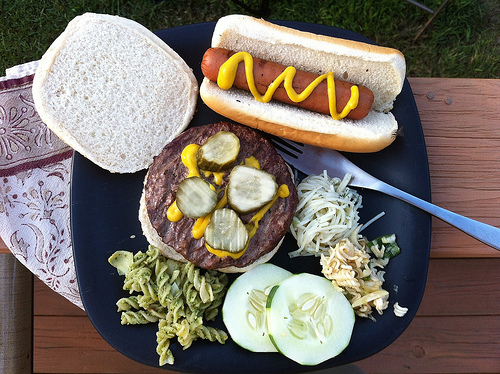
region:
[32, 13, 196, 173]
Plain hamburger bun top on plate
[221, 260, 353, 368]
Cucumber slices sitting on plate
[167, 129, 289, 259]
Pickes and mustard on top of hamburger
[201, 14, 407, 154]
Hotdog with mustard in a bun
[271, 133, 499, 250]
Fork sitting on side of plate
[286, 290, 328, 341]
Seeds in middle of cucumber slice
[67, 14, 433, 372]
Food sitting on blue plate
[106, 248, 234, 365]
Pasta salad sitting on blue plate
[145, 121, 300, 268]
Hamburger patty sitting on bun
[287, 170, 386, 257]
Plain noodles sitting on plate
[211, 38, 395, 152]
hot dog on bun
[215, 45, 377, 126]
mustard on hot dog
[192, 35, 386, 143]
bun is white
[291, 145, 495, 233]
steel spoon on blue plate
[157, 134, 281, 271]
brown hamburger on bun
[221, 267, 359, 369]
green and sliced cucumbers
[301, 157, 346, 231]
white noodles on plate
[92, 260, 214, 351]
light green pasta salad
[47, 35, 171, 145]
half of white bun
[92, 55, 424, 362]
plate on wooden table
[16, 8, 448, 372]
A plate with hamburger and hotdog on it.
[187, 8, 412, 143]
A hotdog on a bun with mustard.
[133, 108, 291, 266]
A hamburger on a bun with pickles and mustard.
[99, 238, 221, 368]
Small amount of pasta salad.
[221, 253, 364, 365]
Two slices of cucumbers.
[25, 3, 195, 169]
The top of a hamburger bun with nothing on it.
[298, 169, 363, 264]
Small amount of cole slaw.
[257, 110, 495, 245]
A silver fork.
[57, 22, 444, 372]
A square plate with rounded edges.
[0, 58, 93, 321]
A napkin under the plate with a pattern on it.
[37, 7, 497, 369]
a plate with food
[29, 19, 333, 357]
a plate on a table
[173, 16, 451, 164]
a hotdog on a plate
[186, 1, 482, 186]
a hotdog on a bun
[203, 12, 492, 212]
a hotdog with mustard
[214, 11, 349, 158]
mustard on hotdog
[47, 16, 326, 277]
a hamburger on plate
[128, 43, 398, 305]
a hamburger on buns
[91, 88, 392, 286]
a hamburger on pickles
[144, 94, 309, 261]
hamburger with mustard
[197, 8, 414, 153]
Hot dog on white bun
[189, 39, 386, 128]
Yellow mustard on hot dog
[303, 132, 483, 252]
Silver fork on plate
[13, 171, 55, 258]
Napkin under plate on table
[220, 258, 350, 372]
Cucumber slices on a plate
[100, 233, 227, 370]
Plasta on a black plate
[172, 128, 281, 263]
Pickle slices on a hambuger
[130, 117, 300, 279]
Mustard and pickles on a hamburger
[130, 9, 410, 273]
Hamburger and hot dog on plate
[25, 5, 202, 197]
Top of a hamburger bun